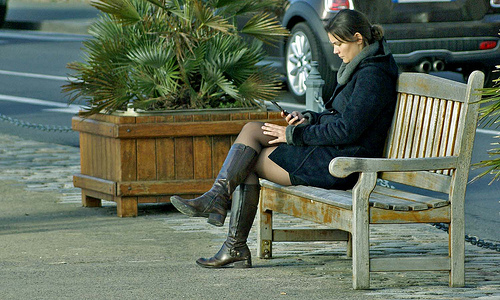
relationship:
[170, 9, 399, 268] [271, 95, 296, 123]
bird viewing phone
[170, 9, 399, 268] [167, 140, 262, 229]
bird wearing boot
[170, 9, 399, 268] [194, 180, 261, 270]
bird wearing boot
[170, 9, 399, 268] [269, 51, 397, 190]
bird wearing coat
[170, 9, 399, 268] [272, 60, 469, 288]
bird sitting in bench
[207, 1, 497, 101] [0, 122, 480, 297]
vehicle parked near sidewalk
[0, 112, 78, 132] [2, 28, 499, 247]
chain in front of road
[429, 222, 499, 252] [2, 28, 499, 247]
chain in front of road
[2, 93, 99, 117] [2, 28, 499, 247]
line on road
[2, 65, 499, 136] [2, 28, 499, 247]
line on road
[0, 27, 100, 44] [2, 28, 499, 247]
line on road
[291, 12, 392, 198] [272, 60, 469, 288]
women sitting on bench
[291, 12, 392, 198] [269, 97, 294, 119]
women sitting with phone.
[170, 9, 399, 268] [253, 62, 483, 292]
bird sitting on bench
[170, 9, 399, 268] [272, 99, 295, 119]
bird with phone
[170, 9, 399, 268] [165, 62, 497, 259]
bird on bench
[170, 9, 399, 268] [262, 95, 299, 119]
bird with phone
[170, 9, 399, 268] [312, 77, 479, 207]
bird sitting on bench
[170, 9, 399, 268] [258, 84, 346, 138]
bird with phone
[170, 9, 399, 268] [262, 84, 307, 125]
bird with phone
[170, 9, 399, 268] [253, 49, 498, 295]
bird sitting on bench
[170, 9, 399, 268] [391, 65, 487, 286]
bird sitting on bench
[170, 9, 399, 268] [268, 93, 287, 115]
bird holding phone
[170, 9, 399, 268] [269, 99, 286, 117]
bird holding phone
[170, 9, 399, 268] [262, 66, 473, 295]
bird on bench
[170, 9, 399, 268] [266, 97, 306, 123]
bird holding phone